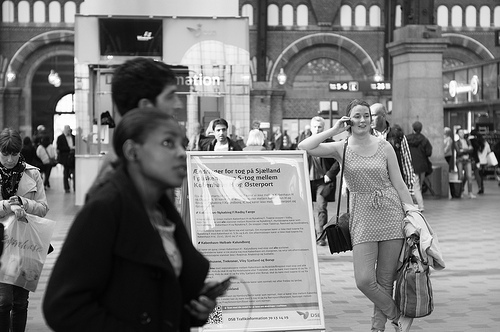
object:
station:
[0, 0, 500, 331]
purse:
[393, 233, 435, 321]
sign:
[187, 149, 331, 332]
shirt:
[211, 143, 230, 150]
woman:
[295, 95, 426, 330]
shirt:
[339, 137, 407, 249]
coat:
[397, 199, 448, 279]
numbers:
[329, 82, 348, 90]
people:
[38, 106, 233, 331]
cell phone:
[343, 116, 352, 129]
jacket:
[40, 166, 211, 332]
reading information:
[188, 151, 320, 331]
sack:
[1, 209, 62, 296]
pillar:
[385, 23, 449, 197]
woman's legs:
[349, 233, 404, 322]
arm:
[385, 141, 416, 210]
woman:
[0, 125, 55, 332]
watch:
[8, 197, 18, 205]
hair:
[107, 56, 178, 118]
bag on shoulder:
[320, 137, 353, 257]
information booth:
[71, 11, 251, 202]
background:
[1, 1, 499, 331]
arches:
[249, 27, 391, 127]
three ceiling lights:
[0, 63, 65, 88]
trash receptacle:
[446, 178, 468, 201]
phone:
[345, 120, 355, 129]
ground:
[0, 157, 500, 329]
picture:
[1, 1, 500, 331]